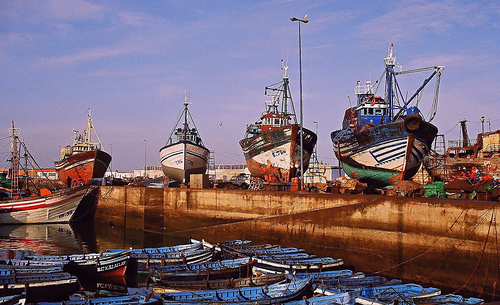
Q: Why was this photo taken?
A: To show all of the ships.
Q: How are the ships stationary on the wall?
A: They are on lifts.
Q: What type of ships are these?
A: Fishing ships.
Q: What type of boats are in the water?
A: Little row boats.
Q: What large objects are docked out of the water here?
A: Boats.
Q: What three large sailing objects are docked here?
A: Boats.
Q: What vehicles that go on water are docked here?
A: Boats.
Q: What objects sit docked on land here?
A: Boats.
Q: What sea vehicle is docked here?
A: Boat.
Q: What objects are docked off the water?
A: Boats.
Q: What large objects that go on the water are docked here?
A: Boats.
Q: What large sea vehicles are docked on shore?
A: Boats.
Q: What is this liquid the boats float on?
A: Water.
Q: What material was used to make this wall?
A: Cement.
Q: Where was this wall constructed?
A: A shipyard.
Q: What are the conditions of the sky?
A: Slightly cloudy.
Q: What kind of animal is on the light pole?
A: A bird.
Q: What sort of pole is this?
A: A light pole.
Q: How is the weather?
A: Few clouds in the sky.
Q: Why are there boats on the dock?
A: For maintenance.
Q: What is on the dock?
A: Four boats.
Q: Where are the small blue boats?
A: On the waterfront of the dock.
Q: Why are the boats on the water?
A: For rent.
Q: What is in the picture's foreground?
A: Small blue boats.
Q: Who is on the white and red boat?
A: Male worker.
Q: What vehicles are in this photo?
A: Ships and boats.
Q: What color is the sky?
A: Blue.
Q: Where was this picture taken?
A: A marina.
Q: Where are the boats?
A: In the water.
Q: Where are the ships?
A: On a dry dock.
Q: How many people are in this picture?
A: Zero.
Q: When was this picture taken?
A: Day time.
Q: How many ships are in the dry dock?
A: Four.